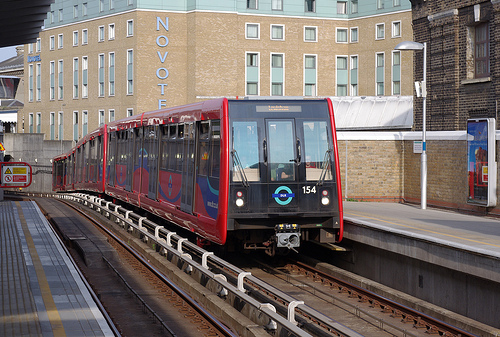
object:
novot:
[149, 13, 173, 112]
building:
[0, 1, 499, 229]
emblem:
[268, 181, 300, 207]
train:
[29, 87, 363, 271]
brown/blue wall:
[198, 35, 237, 89]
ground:
[429, 218, 463, 231]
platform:
[0, 184, 126, 336]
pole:
[417, 36, 436, 215]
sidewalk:
[337, 195, 499, 259]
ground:
[400, 207, 407, 214]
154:
[297, 182, 322, 197]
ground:
[396, 213, 420, 227]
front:
[207, 89, 355, 264]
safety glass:
[216, 90, 344, 189]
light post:
[389, 37, 439, 214]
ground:
[360, 206, 383, 212]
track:
[167, 261, 499, 336]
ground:
[18, 252, 492, 335]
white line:
[20, 192, 122, 336]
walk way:
[0, 193, 128, 337]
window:
[178, 107, 220, 191]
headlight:
[230, 188, 252, 211]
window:
[109, 114, 149, 172]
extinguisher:
[223, 145, 328, 222]